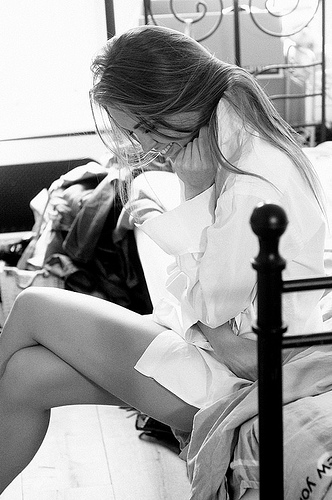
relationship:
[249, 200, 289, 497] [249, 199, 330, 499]
post on bed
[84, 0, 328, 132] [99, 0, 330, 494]
headboard on bed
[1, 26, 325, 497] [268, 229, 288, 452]
woman on bed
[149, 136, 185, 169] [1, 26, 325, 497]
smile on woman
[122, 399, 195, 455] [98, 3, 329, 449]
shoes next to bed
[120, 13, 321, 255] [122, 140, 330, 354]
bed with sheets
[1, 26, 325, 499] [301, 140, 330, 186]
woman on bed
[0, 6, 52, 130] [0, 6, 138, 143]
window with light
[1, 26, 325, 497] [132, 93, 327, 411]
woman wearing shirt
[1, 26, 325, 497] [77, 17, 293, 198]
woman with head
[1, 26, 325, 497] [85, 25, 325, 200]
woman with hair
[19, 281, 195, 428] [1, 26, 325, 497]
thigh of woman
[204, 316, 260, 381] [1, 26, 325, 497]
hand on woman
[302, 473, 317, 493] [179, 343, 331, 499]
letter "y" on blanket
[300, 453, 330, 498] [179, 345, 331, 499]
new york on sheets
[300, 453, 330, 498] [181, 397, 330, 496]
new york printed sheets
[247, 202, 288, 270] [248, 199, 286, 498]
round part of bed post